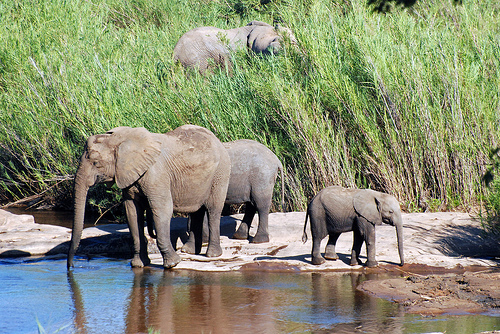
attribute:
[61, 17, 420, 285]
elephant — four, family, water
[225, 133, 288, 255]
elephant — back , larger one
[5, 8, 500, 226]
grass — tall, green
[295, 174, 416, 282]
elephant — baby, drinking, young, small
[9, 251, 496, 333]
water — small, calm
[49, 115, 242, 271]
elephant — drinking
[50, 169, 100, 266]
trunk — wet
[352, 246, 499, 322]
rocks — wet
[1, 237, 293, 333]
stream — blue